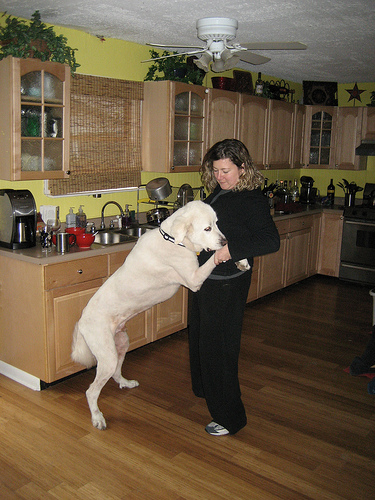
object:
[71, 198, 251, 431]
dog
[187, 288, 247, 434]
pants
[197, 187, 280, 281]
shirt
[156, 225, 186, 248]
collar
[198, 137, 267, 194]
hair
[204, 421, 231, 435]
sneakers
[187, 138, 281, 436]
woman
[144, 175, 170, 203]
pots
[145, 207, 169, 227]
strainer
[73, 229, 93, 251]
bowls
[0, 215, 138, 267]
counter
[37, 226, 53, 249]
mug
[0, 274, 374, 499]
floor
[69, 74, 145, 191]
window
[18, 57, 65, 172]
cabinet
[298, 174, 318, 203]
mixer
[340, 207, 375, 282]
stove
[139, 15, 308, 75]
fan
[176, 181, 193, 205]
bucket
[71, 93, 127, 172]
shade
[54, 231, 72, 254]
coffee maker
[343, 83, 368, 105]
star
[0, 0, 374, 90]
ceiling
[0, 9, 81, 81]
plants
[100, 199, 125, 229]
faucet